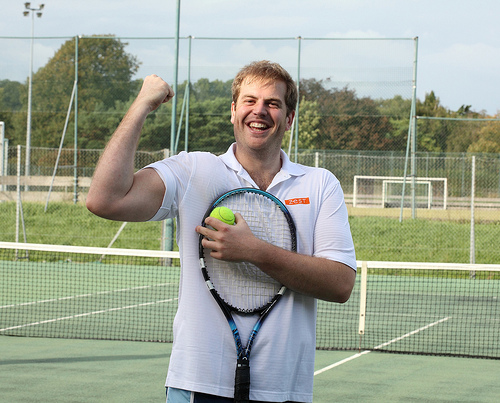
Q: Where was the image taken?
A: It was taken at the field.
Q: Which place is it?
A: It is a field.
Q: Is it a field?
A: Yes, it is a field.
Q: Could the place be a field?
A: Yes, it is a field.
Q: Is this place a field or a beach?
A: It is a field.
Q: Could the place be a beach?
A: No, it is a field.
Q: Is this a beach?
A: No, it is a field.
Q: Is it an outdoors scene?
A: Yes, it is outdoors.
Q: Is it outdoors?
A: Yes, it is outdoors.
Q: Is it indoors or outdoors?
A: It is outdoors.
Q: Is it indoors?
A: No, it is outdoors.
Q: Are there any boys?
A: No, there are no boys.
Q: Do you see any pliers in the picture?
A: No, there are no pliers.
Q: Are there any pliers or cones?
A: No, there are no pliers or cones.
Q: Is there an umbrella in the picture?
A: No, there are no umbrellas.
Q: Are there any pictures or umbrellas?
A: No, there are no umbrellas or pictures.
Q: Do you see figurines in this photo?
A: No, there are no figurines.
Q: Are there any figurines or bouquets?
A: No, there are no figurines or bouquets.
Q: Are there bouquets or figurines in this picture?
A: No, there are no figurines or bouquets.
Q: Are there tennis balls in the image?
A: Yes, there is a tennis ball.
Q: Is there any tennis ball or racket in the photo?
A: Yes, there is a tennis ball.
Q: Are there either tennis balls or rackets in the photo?
A: Yes, there is a tennis ball.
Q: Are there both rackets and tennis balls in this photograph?
A: Yes, there are both a tennis ball and a racket.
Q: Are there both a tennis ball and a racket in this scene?
A: Yes, there are both a tennis ball and a racket.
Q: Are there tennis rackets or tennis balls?
A: Yes, there is a tennis tennis ball.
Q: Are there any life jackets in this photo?
A: No, there are no life jackets.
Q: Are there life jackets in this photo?
A: No, there are no life jackets.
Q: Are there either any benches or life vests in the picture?
A: No, there are no life vests or benches.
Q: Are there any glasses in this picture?
A: No, there are no glasses.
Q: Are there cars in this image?
A: No, there are no cars.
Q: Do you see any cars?
A: No, there are no cars.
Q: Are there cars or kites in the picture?
A: No, there are no cars or kites.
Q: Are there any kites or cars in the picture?
A: No, there are no cars or kites.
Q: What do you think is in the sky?
A: The clouds are in the sky.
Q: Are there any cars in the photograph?
A: No, there are no cars.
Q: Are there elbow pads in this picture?
A: No, there are no elbow pads.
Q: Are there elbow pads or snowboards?
A: No, there are no elbow pads or snowboards.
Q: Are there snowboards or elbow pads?
A: No, there are no elbow pads or snowboards.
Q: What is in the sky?
A: The clouds are in the sky.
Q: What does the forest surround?
A: The forest surrounds the field.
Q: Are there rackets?
A: Yes, there is a racket.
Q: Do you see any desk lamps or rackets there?
A: Yes, there is a racket.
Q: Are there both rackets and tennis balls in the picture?
A: Yes, there are both a racket and a tennis ball.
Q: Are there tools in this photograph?
A: No, there are no tools.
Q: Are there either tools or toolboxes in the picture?
A: No, there are no tools or toolboxes.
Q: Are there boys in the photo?
A: No, there are no boys.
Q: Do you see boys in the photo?
A: No, there are no boys.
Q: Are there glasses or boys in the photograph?
A: No, there are no boys or glasses.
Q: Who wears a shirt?
A: The man wears a shirt.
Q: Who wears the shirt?
A: The man wears a shirt.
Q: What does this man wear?
A: The man wears a shirt.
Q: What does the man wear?
A: The man wears a shirt.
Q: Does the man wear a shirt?
A: Yes, the man wears a shirt.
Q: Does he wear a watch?
A: No, the man wears a shirt.